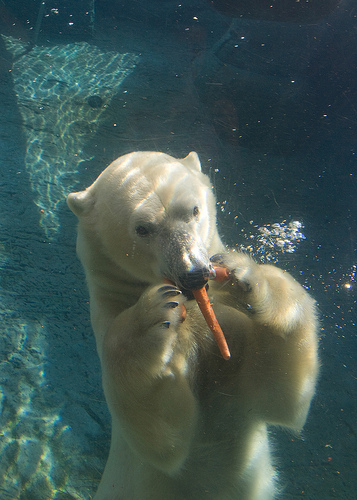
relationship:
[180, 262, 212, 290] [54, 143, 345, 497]
nose of bear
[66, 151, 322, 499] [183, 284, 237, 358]
bear eating carrot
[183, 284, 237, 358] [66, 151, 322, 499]
carrot eating by bear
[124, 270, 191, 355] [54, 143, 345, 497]
paw of bear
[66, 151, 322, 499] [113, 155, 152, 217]
bear has fur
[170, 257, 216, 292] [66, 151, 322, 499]
nose of bear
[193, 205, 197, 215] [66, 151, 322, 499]
eye of bear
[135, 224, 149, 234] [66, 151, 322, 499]
eye of bear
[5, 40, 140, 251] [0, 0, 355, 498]
reflection on water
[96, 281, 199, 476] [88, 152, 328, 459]
right arm belonging to bear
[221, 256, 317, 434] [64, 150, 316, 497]
arm belonging to bears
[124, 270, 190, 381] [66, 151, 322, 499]
paw belonging to bear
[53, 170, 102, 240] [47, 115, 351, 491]
ear belonging to bear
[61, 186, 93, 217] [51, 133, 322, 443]
bear ear belonging to bear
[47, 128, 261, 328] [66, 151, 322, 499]
head belonging to bear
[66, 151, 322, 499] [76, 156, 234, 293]
bear has face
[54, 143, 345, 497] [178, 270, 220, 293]
bear has mouth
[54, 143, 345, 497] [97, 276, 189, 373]
bear has arm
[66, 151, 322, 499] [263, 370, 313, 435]
bear has elbow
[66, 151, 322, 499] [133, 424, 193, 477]
bear has elbow